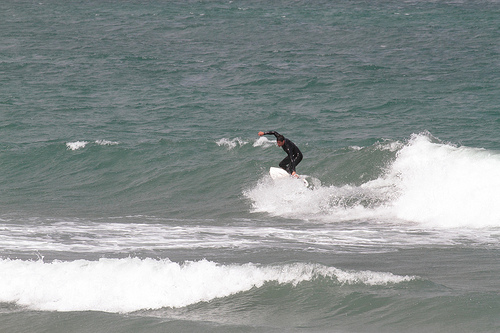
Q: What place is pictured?
A: It is an ocean.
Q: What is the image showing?
A: It is showing an ocean.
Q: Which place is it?
A: It is an ocean.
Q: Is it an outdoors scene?
A: Yes, it is outdoors.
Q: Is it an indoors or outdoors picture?
A: It is outdoors.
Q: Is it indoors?
A: No, it is outdoors.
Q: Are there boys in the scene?
A: No, there are no boys.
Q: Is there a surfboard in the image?
A: Yes, there is a surfboard.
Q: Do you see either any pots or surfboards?
A: Yes, there is a surfboard.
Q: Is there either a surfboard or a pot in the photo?
A: Yes, there is a surfboard.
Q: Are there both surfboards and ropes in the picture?
A: No, there is a surfboard but no ropes.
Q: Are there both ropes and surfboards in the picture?
A: No, there is a surfboard but no ropes.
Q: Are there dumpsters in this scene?
A: No, there are no dumpsters.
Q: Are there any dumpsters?
A: No, there are no dumpsters.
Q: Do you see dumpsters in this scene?
A: No, there are no dumpsters.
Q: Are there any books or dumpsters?
A: No, there are no dumpsters or books.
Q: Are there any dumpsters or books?
A: No, there are no dumpsters or books.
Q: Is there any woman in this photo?
A: No, there are no women.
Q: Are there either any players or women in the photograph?
A: No, there are no women or players.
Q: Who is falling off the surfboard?
A: The man is falling off the surfboard.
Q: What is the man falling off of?
A: The man is falling off the surfboard.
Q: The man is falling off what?
A: The man is falling off the surfboard.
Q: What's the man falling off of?
A: The man is falling off the surfboard.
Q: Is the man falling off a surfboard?
A: Yes, the man is falling off a surfboard.